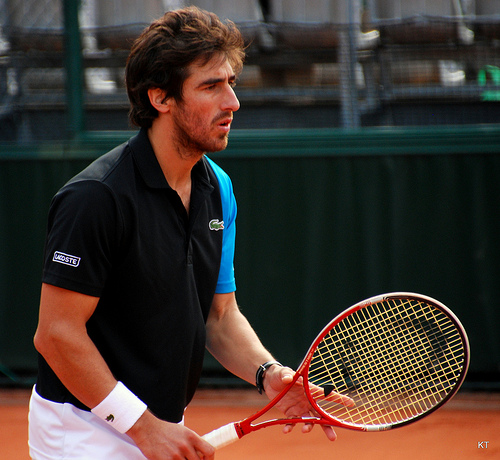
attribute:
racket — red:
[147, 290, 470, 460]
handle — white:
[180, 422, 240, 452]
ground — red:
[0, 388, 498, 460]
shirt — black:
[33, 125, 235, 424]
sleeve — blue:
[205, 156, 238, 295]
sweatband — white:
[91, 380, 148, 436]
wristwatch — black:
[255, 360, 281, 397]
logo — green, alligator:
[209, 219, 225, 232]